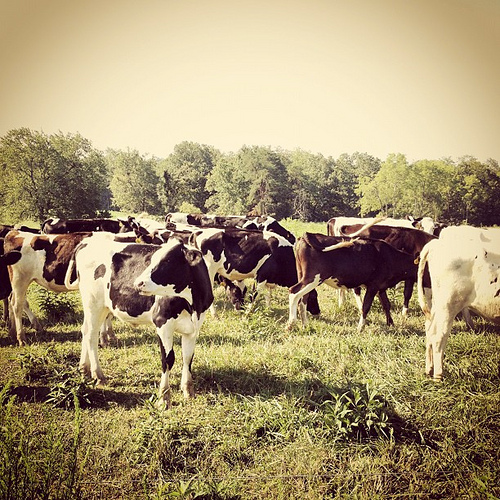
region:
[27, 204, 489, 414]
herd of cows in a field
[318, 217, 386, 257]
two wagging cow tails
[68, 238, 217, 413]
black and white cow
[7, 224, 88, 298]
brown and white cow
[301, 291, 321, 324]
head of grazing cow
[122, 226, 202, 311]
cow looking to the left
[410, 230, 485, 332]
white rear quarter of cow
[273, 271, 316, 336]
back legs of cow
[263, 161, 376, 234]
trees in the background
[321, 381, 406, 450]
weeds in the grass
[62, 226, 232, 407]
Large black and white cow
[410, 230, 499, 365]
Large black and white cow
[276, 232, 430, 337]
Large black and white cow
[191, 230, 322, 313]
Large black and white cow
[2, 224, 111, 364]
Large black and white cow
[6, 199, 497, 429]
Large group of cows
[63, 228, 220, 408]
Cow standing in a field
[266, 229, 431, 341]
Cow standing in a field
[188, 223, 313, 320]
Cow standing in a field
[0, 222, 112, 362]
Cow standing in a field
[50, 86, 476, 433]
several cows on pasture.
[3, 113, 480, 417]
large croup of cows on pasture.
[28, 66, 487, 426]
a large amount of cows on pasture.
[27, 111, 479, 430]
multiple cows on a field.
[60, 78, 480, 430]
a great group of cows.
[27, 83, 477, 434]
an impressive amount of cows in a field.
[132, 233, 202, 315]
head of a cow.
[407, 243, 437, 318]
tail of a cow.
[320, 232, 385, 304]
body of a cow.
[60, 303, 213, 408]
legs of a cow.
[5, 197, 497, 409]
a herd of black and white cows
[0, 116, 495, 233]
a line of many trees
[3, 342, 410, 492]
several small shrubs in the field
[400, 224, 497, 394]
two all white cows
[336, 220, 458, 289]
an all black cow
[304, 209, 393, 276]
long swishing tails on cows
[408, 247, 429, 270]
ear tag on a cow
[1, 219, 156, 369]
a somewhat skinny cow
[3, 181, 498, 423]
many cows all facing the same direction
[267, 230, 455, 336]
a mostly black cow is walking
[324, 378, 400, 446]
cluster of weeds growing in the grass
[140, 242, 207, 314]
cows head looking left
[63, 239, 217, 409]
body of a cow facing right while his head faces left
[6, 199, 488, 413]
herd of cows grazing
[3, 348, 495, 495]
patch of grass in front of cows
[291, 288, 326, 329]
cows head leaning down to eat grass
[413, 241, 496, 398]
white hind legs of a cow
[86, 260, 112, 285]
black spot on a cow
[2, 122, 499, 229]
row of trees behind the cows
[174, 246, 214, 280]
cows ear protruding from its head